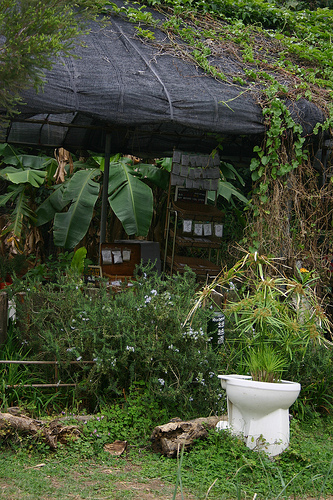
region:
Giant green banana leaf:
[105, 160, 158, 241]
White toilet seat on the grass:
[213, 365, 297, 459]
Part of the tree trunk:
[146, 405, 242, 456]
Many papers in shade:
[162, 142, 227, 203]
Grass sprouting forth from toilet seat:
[241, 339, 289, 392]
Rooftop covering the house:
[2, 0, 326, 161]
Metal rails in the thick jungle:
[0, 356, 107, 405]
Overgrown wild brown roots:
[251, 78, 332, 287]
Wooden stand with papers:
[165, 194, 228, 309]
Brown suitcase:
[96, 235, 150, 296]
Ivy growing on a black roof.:
[118, 3, 328, 190]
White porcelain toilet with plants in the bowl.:
[153, 291, 313, 455]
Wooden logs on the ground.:
[11, 397, 245, 467]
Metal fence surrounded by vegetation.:
[1, 338, 155, 417]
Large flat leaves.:
[3, 127, 172, 274]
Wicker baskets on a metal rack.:
[164, 149, 239, 300]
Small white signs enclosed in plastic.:
[97, 237, 151, 271]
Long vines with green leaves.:
[241, 80, 330, 329]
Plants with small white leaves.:
[59, 279, 217, 413]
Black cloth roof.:
[11, 6, 321, 138]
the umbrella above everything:
[1, 6, 326, 154]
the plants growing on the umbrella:
[1, 1, 323, 106]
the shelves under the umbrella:
[81, 145, 229, 300]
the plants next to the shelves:
[9, 259, 331, 398]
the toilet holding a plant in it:
[211, 374, 298, 459]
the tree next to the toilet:
[154, 418, 232, 455]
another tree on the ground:
[4, 407, 83, 457]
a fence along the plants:
[1, 352, 99, 414]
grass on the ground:
[180, 425, 317, 498]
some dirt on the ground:
[12, 461, 161, 498]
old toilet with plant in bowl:
[209, 342, 318, 450]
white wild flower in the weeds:
[138, 281, 183, 326]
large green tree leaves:
[49, 151, 168, 250]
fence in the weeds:
[9, 342, 107, 408]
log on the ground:
[1, 411, 105, 449]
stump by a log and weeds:
[67, 410, 149, 471]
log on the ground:
[150, 405, 216, 465]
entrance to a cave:
[66, 21, 319, 170]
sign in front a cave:
[161, 148, 259, 281]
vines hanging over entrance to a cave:
[231, 74, 331, 196]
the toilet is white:
[216, 374, 304, 460]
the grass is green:
[103, 377, 195, 405]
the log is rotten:
[140, 417, 212, 457]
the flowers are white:
[168, 326, 213, 349]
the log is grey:
[155, 420, 209, 452]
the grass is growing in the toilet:
[231, 353, 310, 391]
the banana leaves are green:
[55, 193, 158, 240]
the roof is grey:
[106, 62, 236, 112]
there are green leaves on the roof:
[200, 32, 331, 83]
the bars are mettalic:
[16, 355, 77, 407]